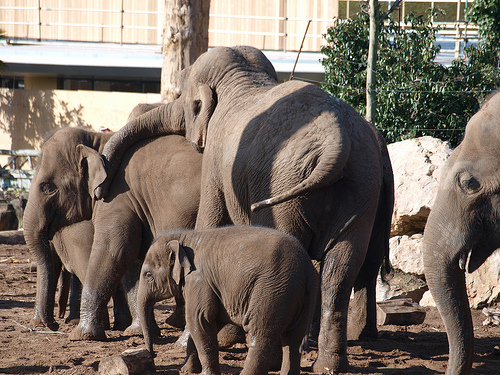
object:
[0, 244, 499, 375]
ground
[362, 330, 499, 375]
shadows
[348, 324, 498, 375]
dirt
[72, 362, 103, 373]
prints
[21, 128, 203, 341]
elephant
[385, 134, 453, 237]
boulder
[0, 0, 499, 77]
balcony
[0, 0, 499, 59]
fence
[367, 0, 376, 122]
fence post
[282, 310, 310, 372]
elephant leg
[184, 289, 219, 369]
elephant leg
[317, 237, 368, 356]
elephant leg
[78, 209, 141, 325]
elephant leg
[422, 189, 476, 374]
elephant trunk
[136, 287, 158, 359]
elephant trunk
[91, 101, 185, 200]
elephant trunk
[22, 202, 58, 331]
elephant trunk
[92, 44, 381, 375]
elephant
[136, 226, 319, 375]
elephant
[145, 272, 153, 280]
elephant eye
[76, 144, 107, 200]
elephant ear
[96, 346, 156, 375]
rock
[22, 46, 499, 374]
animals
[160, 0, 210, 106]
pole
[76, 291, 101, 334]
powder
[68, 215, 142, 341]
leg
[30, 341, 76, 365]
dirt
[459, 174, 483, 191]
eye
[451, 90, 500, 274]
face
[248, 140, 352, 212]
tail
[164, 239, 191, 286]
ear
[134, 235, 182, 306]
head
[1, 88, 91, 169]
shadows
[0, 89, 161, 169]
wall